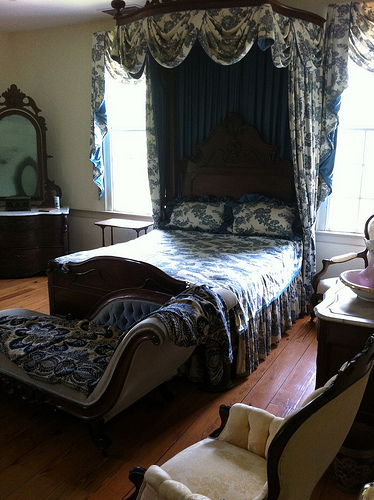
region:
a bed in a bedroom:
[59, 146, 306, 334]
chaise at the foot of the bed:
[2, 283, 225, 398]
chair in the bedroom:
[128, 357, 368, 488]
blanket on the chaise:
[158, 288, 216, 339]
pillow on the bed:
[231, 195, 299, 250]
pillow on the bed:
[162, 193, 226, 238]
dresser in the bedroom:
[2, 85, 71, 254]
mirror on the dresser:
[2, 91, 51, 201]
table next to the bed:
[92, 207, 151, 249]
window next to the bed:
[90, 28, 154, 211]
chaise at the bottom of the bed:
[11, 293, 199, 418]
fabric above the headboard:
[120, 8, 306, 84]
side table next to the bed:
[101, 203, 151, 245]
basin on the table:
[340, 220, 373, 302]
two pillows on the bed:
[175, 187, 306, 254]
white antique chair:
[117, 338, 367, 498]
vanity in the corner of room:
[3, 75, 80, 282]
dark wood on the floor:
[265, 342, 316, 401]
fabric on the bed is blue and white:
[160, 219, 264, 282]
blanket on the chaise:
[6, 297, 143, 402]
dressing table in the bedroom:
[0, 84, 56, 265]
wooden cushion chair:
[144, 367, 364, 498]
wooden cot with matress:
[88, 75, 315, 352]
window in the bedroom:
[336, 65, 372, 235]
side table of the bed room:
[96, 216, 146, 242]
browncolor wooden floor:
[264, 333, 301, 405]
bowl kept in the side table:
[341, 263, 371, 299]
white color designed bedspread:
[144, 232, 274, 283]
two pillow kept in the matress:
[181, 195, 286, 234]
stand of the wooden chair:
[82, 414, 114, 454]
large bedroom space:
[1, 5, 370, 493]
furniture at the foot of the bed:
[2, 290, 215, 426]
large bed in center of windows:
[78, 30, 373, 332]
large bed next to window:
[62, 112, 351, 354]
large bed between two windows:
[56, 154, 321, 367]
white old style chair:
[128, 342, 373, 497]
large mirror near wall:
[1, 91, 51, 208]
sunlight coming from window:
[104, 86, 148, 207]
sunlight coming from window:
[332, 93, 372, 236]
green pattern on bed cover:
[179, 240, 238, 275]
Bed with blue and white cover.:
[44, 127, 305, 377]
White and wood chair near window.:
[302, 210, 368, 319]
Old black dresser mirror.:
[0, 82, 54, 206]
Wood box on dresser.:
[2, 193, 29, 211]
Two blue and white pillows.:
[159, 192, 302, 236]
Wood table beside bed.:
[91, 214, 148, 242]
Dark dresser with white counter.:
[0, 204, 69, 272]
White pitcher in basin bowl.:
[338, 232, 370, 302]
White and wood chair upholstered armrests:
[127, 342, 365, 495]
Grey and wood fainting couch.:
[0, 283, 211, 441]